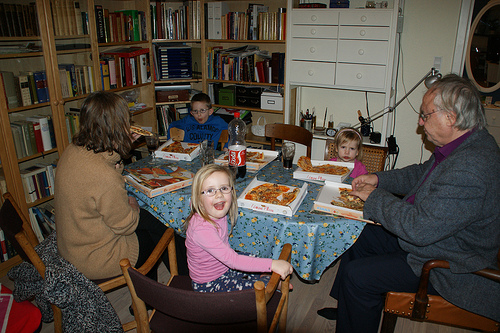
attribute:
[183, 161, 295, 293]
girl — little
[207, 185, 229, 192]
eyes — corrective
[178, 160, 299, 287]
girl — little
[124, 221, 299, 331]
chair — wooden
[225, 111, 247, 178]
bottle — half empty, cola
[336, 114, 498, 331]
coat — grey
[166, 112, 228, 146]
shirt — blue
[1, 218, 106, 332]
sweater — brown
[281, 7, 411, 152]
shelves — wooden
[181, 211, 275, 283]
shirt — long sleeve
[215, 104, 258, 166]
bottle — Coca-Cola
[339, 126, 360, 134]
headband — light colored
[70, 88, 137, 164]
hair — brown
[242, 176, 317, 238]
pizza — small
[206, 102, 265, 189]
bottle — soda bottle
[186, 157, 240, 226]
hair — blonde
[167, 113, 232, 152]
shirt — blue